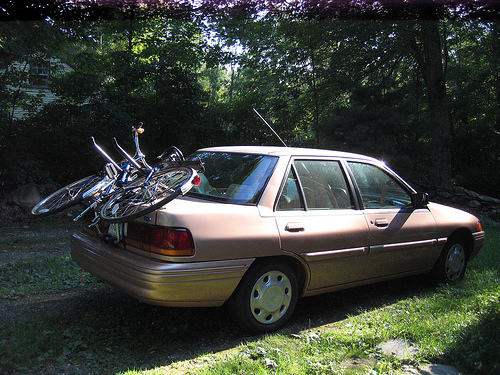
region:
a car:
[247, 140, 355, 312]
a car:
[211, 192, 306, 318]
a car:
[272, 218, 338, 361]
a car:
[233, 116, 260, 201]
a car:
[248, 150, 302, 267]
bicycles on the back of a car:
[52, 116, 224, 236]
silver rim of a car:
[247, 262, 311, 333]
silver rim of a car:
[435, 240, 468, 285]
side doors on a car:
[263, 149, 443, 289]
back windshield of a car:
[165, 141, 298, 213]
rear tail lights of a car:
[97, 217, 217, 264]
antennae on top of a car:
[225, 96, 330, 171]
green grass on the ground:
[337, 306, 475, 370]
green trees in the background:
[93, 14, 395, 152]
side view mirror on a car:
[402, 184, 448, 231]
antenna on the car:
[246, 89, 312, 143]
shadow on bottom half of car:
[153, 205, 497, 305]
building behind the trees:
[24, 9, 135, 138]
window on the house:
[19, 45, 62, 109]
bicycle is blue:
[95, 153, 180, 210]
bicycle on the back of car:
[47, 133, 211, 258]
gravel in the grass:
[25, 225, 72, 285]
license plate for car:
[82, 213, 143, 260]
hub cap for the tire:
[251, 269, 307, 334]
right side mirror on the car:
[403, 193, 443, 205]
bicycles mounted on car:
[25, 120, 202, 242]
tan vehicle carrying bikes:
[30, 130, 490, 350]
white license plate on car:
[89, 218, 126, 241]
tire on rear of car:
[240, 257, 303, 337]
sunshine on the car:
[136, 140, 478, 240]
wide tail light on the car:
[116, 220, 195, 261]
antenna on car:
[245, 91, 291, 149]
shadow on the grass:
[428, 290, 494, 372]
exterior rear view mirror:
[403, 190, 433, 210]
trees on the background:
[17, 47, 425, 147]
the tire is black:
[244, 300, 250, 315]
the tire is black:
[244, 291, 251, 313]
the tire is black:
[237, 297, 257, 337]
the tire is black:
[243, 296, 253, 339]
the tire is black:
[237, 302, 252, 328]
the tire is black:
[244, 310, 255, 327]